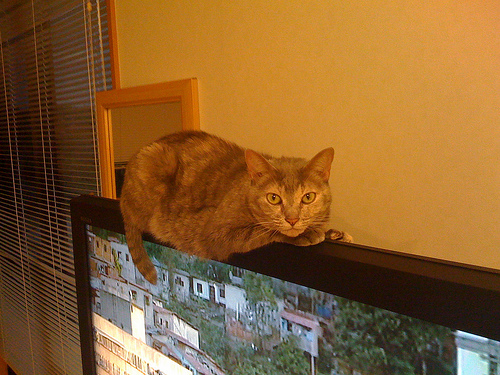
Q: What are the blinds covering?
A: Window.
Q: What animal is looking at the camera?
A: Cat.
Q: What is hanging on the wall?
A: Mirror.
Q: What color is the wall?
A: Yellow.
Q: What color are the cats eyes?
A: Green.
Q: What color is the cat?
A: Gray.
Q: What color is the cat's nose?
A: Pink.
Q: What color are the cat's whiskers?
A: White.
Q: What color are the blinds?
A: White.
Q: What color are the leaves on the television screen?
A: Green.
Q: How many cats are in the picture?
A: 1.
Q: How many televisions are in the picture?
A: 1.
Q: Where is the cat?
A: On the television.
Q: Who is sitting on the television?
A: The cat.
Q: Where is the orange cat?
A: Perched on the television edge.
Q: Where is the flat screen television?
A: It is under the orange striped cat.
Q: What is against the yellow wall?
A: A big screen television.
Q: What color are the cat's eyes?
A: They are golden in color.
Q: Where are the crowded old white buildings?
A: On the television screen.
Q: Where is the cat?
A: On top of the tv.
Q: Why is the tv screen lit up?
A: Turned on.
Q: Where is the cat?
A: On tv.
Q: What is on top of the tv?
A: Cat.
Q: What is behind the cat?
A: Mirror.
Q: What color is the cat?
A: Gray striped.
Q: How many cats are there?
A: One.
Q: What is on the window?
A: Blinds.